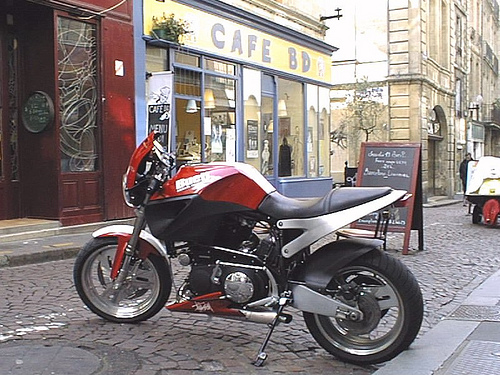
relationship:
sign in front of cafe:
[355, 138, 430, 250] [144, 0, 343, 197]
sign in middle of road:
[355, 138, 430, 250] [0, 197, 498, 372]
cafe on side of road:
[153, 7, 358, 183] [0, 197, 498, 372]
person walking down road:
[459, 153, 470, 201] [426, 202, 491, 299]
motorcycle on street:
[72, 129, 425, 366] [424, 202, 463, 312]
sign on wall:
[18, 90, 58, 136] [17, 12, 54, 219]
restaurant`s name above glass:
[212, 19, 310, 74] [174, 50, 329, 180]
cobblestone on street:
[441, 219, 473, 270] [29, 170, 498, 311]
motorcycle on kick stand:
[72, 129, 425, 366] [251, 291, 292, 366]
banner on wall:
[141, 67, 176, 161] [132, 5, 341, 200]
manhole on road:
[4, 335, 104, 374] [0, 197, 498, 373]